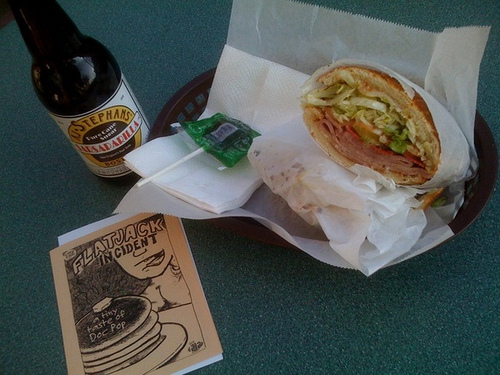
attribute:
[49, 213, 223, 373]
greeting card — small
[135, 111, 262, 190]
lollipop — yummy, green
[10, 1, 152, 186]
bottle — glass, brown, dark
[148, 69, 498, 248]
tray — plastic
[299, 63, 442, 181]
food — wrapped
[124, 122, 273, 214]
napkins — paper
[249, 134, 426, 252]
paper — white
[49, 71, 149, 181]
label — white, yellow, brown, red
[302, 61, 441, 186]
sandwhich — half, cold cut, wrapped, turkey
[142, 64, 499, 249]
basket — plastic, brown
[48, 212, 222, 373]
book — brown, paper, tan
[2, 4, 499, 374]
table — blue, speckled